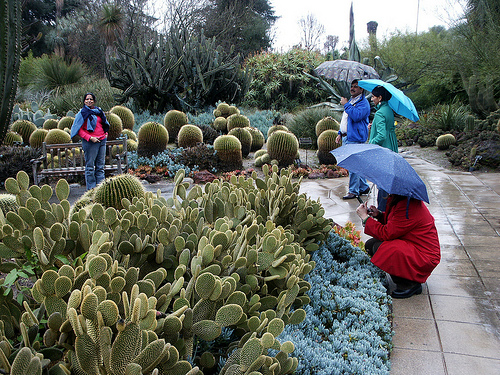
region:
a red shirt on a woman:
[73, 116, 107, 142]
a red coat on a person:
[358, 196, 455, 284]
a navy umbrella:
[325, 137, 441, 210]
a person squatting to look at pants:
[344, 166, 449, 316]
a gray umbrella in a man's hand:
[306, 53, 379, 91]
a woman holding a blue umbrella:
[356, 73, 422, 213]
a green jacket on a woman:
[361, 100, 402, 160]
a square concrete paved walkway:
[370, 142, 497, 371]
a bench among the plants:
[26, 139, 152, 195]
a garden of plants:
[0, 195, 373, 373]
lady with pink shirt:
[69, 88, 131, 193]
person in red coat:
[333, 173, 455, 306]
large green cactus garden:
[62, 157, 210, 349]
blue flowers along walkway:
[286, 254, 431, 370]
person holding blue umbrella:
[309, 127, 482, 312]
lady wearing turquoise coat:
[352, 69, 433, 173]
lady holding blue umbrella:
[357, 54, 436, 162]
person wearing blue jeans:
[59, 84, 124, 169]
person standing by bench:
[28, 70, 210, 222]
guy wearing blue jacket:
[321, 59, 396, 174]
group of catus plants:
[53, 201, 271, 366]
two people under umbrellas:
[310, 56, 415, 145]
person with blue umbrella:
[326, 136, 441, 306]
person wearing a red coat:
[323, 136, 463, 299]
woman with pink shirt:
[69, 73, 119, 188]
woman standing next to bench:
[20, 83, 150, 195]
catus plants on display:
[129, 99, 331, 191]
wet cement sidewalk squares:
[438, 169, 495, 360]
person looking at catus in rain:
[180, 140, 460, 302]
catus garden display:
[108, 21, 318, 298]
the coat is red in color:
[371, 195, 451, 287]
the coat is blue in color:
[336, 91, 373, 137]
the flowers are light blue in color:
[308, 267, 372, 344]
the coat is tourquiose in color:
[367, 105, 410, 145]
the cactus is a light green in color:
[187, 230, 294, 297]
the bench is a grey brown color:
[28, 137, 158, 179]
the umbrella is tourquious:
[356, 72, 428, 123]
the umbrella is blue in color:
[324, 139, 448, 211]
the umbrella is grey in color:
[308, 53, 387, 86]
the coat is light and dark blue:
[70, 105, 119, 150]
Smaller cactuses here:
[6, 166, 346, 373]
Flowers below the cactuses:
[323, 219, 428, 371]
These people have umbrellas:
[295, 27, 475, 274]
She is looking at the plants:
[65, 82, 136, 196]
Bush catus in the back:
[96, 72, 381, 194]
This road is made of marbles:
[378, 129, 499, 336]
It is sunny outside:
[248, 4, 470, 98]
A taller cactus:
[3, 5, 103, 183]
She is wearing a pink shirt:
[63, 86, 134, 188]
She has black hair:
[62, 75, 127, 179]